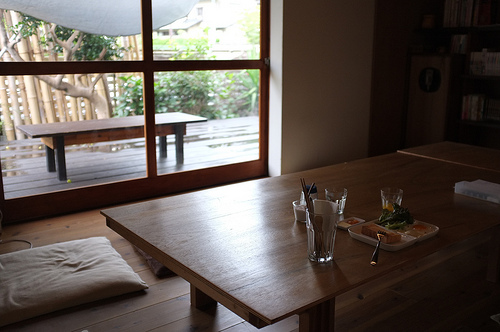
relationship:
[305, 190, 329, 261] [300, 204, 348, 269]
utensils sitting in glass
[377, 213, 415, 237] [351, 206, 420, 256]
food inside of tray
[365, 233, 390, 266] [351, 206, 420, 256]
fork lying on tray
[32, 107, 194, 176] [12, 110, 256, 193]
bench sits on porch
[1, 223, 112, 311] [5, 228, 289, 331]
pillow lying on floor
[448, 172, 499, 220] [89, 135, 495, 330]
napkins lying on table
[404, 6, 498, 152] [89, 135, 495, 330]
shelves behind table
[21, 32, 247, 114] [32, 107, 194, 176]
tree behind bench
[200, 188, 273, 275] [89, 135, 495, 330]
light reflects from table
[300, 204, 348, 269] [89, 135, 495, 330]
glass sitting on table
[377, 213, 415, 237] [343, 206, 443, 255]
food sitting on tray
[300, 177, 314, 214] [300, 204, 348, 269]
utensils sitting in glass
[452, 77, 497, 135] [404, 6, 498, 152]
books sitting on shelves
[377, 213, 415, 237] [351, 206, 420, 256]
food sitting in tray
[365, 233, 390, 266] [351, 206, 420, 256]
fork hangs on tray